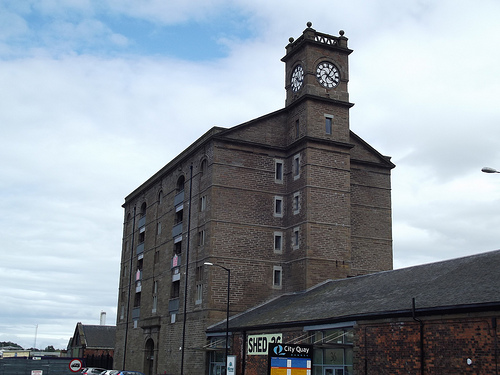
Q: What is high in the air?
A: Clock.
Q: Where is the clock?
A: Top of building.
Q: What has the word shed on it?
A: Building.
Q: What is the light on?
A: Pole.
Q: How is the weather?
A: Cloudy.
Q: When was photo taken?
A: Daytime.